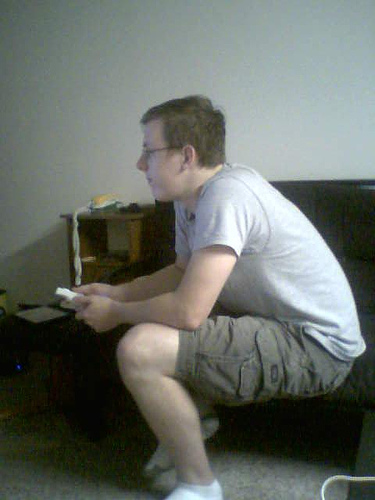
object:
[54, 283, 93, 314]
game controller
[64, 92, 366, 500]
man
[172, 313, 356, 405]
cargo shorts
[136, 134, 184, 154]
eye glasses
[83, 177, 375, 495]
couch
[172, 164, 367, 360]
shirt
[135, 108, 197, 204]
face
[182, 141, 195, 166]
ear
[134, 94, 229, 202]
head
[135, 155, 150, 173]
nose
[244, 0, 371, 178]
wall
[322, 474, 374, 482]
cord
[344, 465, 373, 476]
piece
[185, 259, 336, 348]
man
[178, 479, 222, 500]
socks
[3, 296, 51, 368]
stand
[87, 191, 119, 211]
phone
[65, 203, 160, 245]
stand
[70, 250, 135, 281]
shelfs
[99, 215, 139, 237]
furntiture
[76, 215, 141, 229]
piece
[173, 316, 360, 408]
shorts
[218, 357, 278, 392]
pair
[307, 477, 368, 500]
wire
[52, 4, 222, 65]
wall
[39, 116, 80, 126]
colored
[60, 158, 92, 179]
white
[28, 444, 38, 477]
carpet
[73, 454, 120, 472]
color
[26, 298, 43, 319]
piece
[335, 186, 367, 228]
futon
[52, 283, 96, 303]
remote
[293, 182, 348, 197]
sofa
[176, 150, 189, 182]
man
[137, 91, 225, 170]
hair